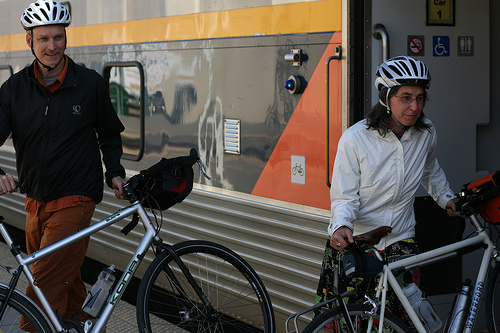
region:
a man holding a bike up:
[0, 10, 137, 271]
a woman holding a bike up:
[341, 62, 461, 331]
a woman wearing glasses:
[379, 91, 436, 117]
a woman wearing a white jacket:
[330, 142, 426, 228]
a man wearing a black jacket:
[59, 63, 113, 150]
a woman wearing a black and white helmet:
[383, 63, 431, 104]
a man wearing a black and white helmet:
[14, 2, 68, 42]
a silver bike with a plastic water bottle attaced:
[53, 220, 178, 330]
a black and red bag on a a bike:
[143, 145, 199, 213]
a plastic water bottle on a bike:
[396, 263, 453, 332]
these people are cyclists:
[22, 6, 455, 268]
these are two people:
[14, 4, 421, 271]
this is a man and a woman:
[28, 25, 412, 288]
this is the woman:
[355, 119, 434, 252]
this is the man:
[10, 40, 132, 260]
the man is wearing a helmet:
[8, 4, 101, 44]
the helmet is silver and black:
[353, 55, 478, 95]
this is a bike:
[24, 193, 209, 312]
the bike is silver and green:
[28, 209, 163, 305]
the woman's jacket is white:
[344, 123, 459, 284]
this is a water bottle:
[82, 265, 115, 316]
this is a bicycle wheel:
[139, 240, 276, 326]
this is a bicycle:
[291, 226, 490, 331]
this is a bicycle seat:
[355, 223, 390, 243]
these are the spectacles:
[393, 93, 424, 102]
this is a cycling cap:
[382, 59, 429, 82]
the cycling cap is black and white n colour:
[382, 60, 432, 84]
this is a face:
[37, 31, 64, 61]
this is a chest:
[12, 87, 87, 149]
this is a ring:
[331, 241, 342, 248]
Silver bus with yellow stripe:
[0, 1, 499, 332]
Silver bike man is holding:
[0, 149, 276, 331]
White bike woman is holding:
[283, 171, 498, 332]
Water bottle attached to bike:
[395, 267, 445, 332]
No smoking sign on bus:
[405, 32, 425, 57]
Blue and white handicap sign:
[430, 33, 451, 59]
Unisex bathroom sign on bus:
[455, 33, 475, 59]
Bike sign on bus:
[289, 153, 306, 185]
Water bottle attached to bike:
[80, 261, 117, 317]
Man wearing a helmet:
[2, 0, 127, 332]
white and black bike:
[0, 202, 275, 332]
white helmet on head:
[376, 55, 429, 93]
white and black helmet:
[19, 2, 71, 29]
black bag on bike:
[136, 160, 196, 212]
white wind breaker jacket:
[333, 119, 457, 246]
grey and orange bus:
[1, 2, 366, 332]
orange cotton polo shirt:
[23, 61, 93, 216]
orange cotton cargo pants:
[18, 204, 95, 332]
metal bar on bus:
[323, 52, 340, 194]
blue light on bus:
[285, 75, 300, 96]